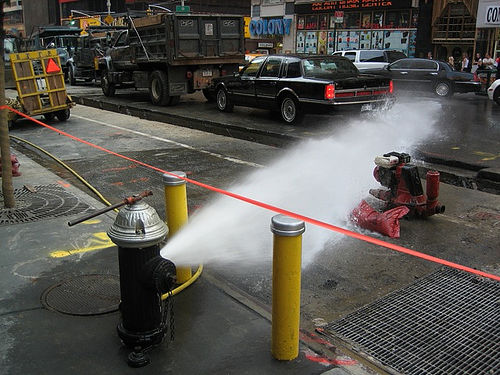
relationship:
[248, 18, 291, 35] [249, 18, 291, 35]
colony on colony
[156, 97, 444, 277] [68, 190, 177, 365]
water from fire hydrant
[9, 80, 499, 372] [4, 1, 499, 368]
street in city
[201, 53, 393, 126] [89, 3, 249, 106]
car behind dump truck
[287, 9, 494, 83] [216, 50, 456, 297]
store on road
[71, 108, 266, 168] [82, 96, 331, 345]
lane marking on lane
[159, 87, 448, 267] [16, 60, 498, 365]
water onto street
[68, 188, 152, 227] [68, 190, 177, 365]
wrench to open fire hydrant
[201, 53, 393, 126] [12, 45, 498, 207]
car in street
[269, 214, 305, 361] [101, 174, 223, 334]
pole next to hydrant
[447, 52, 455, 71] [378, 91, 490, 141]
person along road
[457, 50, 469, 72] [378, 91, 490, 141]
person along road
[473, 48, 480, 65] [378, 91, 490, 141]
person along road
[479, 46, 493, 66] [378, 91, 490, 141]
person along road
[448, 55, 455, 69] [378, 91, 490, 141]
person along road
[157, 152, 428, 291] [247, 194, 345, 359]
orange tape tied to a post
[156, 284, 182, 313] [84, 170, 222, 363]
chain attached to fire hydrant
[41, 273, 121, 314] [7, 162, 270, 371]
cover on sidewalk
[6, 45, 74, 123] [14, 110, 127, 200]
trailer on road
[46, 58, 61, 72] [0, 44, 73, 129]
caution sign on trailer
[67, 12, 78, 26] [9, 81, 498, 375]
light by road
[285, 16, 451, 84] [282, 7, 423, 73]
window by building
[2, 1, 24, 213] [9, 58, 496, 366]
tree next to road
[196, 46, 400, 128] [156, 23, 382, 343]
car in middle of road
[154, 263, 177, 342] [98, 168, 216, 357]
chains on a fire hydrant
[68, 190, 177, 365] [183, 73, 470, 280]
fire hydrant spraying on street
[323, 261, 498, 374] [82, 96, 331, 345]
drain on lane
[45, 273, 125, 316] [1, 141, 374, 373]
black manhole on sidewalk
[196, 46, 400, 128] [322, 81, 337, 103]
car with taillight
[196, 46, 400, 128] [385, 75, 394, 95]
car with taillight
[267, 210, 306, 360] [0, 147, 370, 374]
pole on curb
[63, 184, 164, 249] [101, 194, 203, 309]
wrench on hydrant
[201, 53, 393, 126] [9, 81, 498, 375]
car in road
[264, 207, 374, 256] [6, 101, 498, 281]
line of tape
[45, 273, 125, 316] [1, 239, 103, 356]
black manhole on sidewalk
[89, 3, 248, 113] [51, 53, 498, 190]
dump truck on road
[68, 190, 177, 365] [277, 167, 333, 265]
fire hydrant spraying water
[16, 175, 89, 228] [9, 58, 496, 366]
drainage next to road